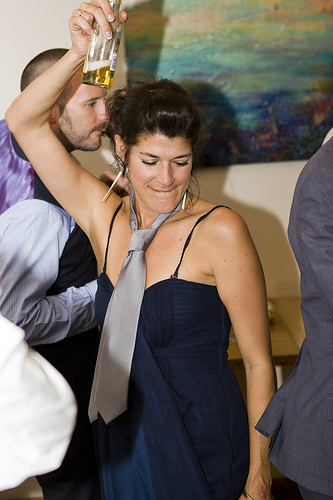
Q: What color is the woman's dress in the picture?
A: Navy.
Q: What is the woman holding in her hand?
A: A beer bottle.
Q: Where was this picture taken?
A: At a party.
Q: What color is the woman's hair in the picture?
A: Black.